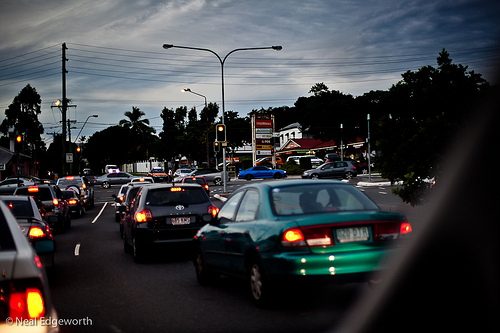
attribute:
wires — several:
[1, 42, 499, 143]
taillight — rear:
[69, 199, 77, 207]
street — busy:
[37, 163, 451, 331]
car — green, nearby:
[190, 175, 412, 302]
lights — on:
[398, 221, 412, 235]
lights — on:
[281, 226, 306, 246]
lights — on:
[133, 210, 146, 226]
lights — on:
[210, 205, 220, 221]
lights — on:
[27, 227, 48, 242]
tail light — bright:
[29, 224, 49, 239]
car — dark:
[2, 191, 56, 267]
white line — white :
[86, 195, 114, 236]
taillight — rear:
[116, 196, 171, 236]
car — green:
[183, 164, 415, 304]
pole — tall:
[59, 37, 72, 152]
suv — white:
[99, 157, 121, 180]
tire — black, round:
[244, 251, 276, 307]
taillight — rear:
[392, 219, 411, 241]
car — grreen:
[241, 162, 421, 282]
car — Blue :
[233, 156, 285, 180]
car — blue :
[236, 162, 288, 180]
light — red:
[64, 140, 95, 167]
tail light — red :
[80, 183, 97, 195]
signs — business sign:
[252, 115, 276, 152]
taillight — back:
[135, 212, 145, 223]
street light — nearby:
[215, 124, 225, 145]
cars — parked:
[163, 147, 428, 306]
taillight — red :
[280, 222, 306, 255]